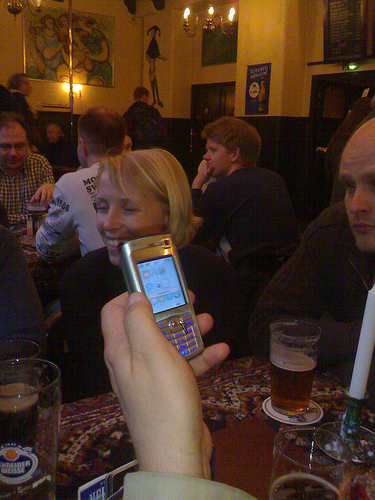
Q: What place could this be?
A: It is a restaurant.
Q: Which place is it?
A: It is a restaurant.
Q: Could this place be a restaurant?
A: Yes, it is a restaurant.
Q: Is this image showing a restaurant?
A: Yes, it is showing a restaurant.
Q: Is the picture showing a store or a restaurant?
A: It is showing a restaurant.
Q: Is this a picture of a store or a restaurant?
A: It is showing a restaurant.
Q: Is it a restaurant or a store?
A: It is a restaurant.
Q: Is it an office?
A: No, it is a restaurant.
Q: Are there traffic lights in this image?
A: No, there are no traffic lights.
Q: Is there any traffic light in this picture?
A: No, there are no traffic lights.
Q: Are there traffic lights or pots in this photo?
A: No, there are no traffic lights or pots.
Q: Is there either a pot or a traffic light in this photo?
A: No, there are no traffic lights or pots.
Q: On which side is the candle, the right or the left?
A: The candle is on the right of the image.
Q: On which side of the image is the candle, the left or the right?
A: The candle is on the right of the image.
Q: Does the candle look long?
A: Yes, the candle is long.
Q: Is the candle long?
A: Yes, the candle is long.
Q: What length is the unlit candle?
A: The candle is long.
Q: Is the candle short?
A: No, the candle is long.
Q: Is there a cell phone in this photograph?
A: Yes, there is a cell phone.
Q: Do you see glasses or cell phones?
A: Yes, there is a cell phone.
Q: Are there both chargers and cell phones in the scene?
A: No, there is a cell phone but no chargers.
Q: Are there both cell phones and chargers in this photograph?
A: No, there is a cell phone but no chargers.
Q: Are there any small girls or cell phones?
A: Yes, there is a small cell phone.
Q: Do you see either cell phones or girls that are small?
A: Yes, the cell phone is small.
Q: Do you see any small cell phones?
A: Yes, there is a small cell phone.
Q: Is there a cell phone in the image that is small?
A: Yes, there is a cell phone that is small.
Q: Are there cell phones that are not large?
A: Yes, there is a small cell phone.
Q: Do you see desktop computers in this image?
A: No, there are no desktop computers.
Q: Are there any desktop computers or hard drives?
A: No, there are no desktop computers or hard drives.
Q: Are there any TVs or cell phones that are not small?
A: No, there is a cell phone but it is small.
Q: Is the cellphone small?
A: Yes, the cellphone is small.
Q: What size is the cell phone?
A: The cell phone is small.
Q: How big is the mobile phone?
A: The mobile phone is small.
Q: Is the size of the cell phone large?
A: No, the cell phone is small.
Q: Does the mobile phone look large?
A: No, the mobile phone is small.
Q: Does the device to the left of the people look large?
A: No, the mobile phone is small.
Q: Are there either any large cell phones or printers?
A: No, there is a cell phone but it is small.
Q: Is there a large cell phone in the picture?
A: No, there is a cell phone but it is small.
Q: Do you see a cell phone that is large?
A: No, there is a cell phone but it is small.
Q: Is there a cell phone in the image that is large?
A: No, there is a cell phone but it is small.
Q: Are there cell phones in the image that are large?
A: No, there is a cell phone but it is small.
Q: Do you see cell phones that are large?
A: No, there is a cell phone but it is small.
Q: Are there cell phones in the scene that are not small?
A: No, there is a cell phone but it is small.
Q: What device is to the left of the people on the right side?
A: The device is a cell phone.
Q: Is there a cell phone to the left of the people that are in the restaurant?
A: Yes, there is a cell phone to the left of the people.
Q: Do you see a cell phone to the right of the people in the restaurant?
A: No, the cell phone is to the left of the people.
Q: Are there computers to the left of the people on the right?
A: No, there is a cell phone to the left of the people.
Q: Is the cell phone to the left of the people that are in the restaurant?
A: Yes, the cell phone is to the left of the people.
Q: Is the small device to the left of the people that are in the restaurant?
A: Yes, the cell phone is to the left of the people.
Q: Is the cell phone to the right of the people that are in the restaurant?
A: No, the cell phone is to the left of the people.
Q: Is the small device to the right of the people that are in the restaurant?
A: No, the cell phone is to the left of the people.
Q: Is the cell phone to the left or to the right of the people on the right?
A: The cell phone is to the left of the people.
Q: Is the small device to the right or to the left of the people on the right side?
A: The cell phone is to the left of the people.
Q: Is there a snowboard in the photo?
A: No, there are no snowboards.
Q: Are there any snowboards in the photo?
A: No, there are no snowboards.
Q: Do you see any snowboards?
A: No, there are no snowboards.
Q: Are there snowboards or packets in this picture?
A: No, there are no snowboards or packets.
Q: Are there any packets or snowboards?
A: No, there are no snowboards or packets.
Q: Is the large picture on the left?
A: Yes, the picture is on the left of the image.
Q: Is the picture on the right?
A: No, the picture is on the left of the image.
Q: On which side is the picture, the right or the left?
A: The picture is on the left of the image.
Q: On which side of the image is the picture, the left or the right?
A: The picture is on the left of the image.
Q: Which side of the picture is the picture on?
A: The picture is on the left of the image.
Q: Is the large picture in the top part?
A: Yes, the picture is in the top of the image.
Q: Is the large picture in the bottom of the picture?
A: No, the picture is in the top of the image.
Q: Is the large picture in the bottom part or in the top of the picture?
A: The picture is in the top of the image.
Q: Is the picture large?
A: Yes, the picture is large.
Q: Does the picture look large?
A: Yes, the picture is large.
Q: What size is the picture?
A: The picture is large.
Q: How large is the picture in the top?
A: The picture is large.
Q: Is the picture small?
A: No, the picture is large.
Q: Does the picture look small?
A: No, the picture is large.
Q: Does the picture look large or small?
A: The picture is large.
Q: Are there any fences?
A: No, there are no fences.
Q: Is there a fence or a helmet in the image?
A: No, there are no fences or helmets.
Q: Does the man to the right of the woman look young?
A: Yes, the man is young.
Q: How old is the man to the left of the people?
A: The man is young.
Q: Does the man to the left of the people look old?
A: No, the man is young.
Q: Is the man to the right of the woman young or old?
A: The man is young.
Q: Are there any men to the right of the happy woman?
A: Yes, there is a man to the right of the woman.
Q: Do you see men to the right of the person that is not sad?
A: Yes, there is a man to the right of the woman.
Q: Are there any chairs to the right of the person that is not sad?
A: No, there is a man to the right of the woman.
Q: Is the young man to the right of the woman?
A: Yes, the man is to the right of the woman.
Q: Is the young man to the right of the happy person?
A: Yes, the man is to the right of the woman.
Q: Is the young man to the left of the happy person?
A: No, the man is to the right of the woman.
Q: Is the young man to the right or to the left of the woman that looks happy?
A: The man is to the right of the woman.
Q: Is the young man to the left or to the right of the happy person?
A: The man is to the right of the woman.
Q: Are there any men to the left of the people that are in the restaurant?
A: Yes, there is a man to the left of the people.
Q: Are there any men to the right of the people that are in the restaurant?
A: No, the man is to the left of the people.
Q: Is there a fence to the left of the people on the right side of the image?
A: No, there is a man to the left of the people.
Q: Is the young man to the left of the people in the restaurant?
A: Yes, the man is to the left of the people.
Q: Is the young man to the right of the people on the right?
A: No, the man is to the left of the people.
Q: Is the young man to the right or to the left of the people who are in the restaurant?
A: The man is to the left of the people.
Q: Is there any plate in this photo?
A: No, there are no plates.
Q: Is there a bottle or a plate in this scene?
A: No, there are no plates or bottles.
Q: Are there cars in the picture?
A: No, there are no cars.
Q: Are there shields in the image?
A: No, there are no shields.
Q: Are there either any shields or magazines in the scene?
A: No, there are no shields or magazines.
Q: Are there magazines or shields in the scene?
A: No, there are no shields or magazines.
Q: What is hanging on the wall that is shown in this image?
A: The poster is hanging on the wall.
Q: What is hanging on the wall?
A: The poster is hanging on the wall.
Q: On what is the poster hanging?
A: The poster is hanging on the wall.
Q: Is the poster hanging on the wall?
A: Yes, the poster is hanging on the wall.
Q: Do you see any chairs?
A: No, there are no chairs.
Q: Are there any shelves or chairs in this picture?
A: No, there are no chairs or shelves.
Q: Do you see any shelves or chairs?
A: No, there are no chairs or shelves.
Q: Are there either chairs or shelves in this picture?
A: No, there are no chairs or shelves.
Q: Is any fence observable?
A: No, there are no fences.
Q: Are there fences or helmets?
A: No, there are no fences or helmets.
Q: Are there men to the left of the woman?
A: Yes, there is a man to the left of the woman.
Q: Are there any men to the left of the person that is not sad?
A: Yes, there is a man to the left of the woman.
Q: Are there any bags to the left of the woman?
A: No, there is a man to the left of the woman.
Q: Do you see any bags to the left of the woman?
A: No, there is a man to the left of the woman.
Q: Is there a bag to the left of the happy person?
A: No, there is a man to the left of the woman.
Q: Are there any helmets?
A: No, there are no helmets.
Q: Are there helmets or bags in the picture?
A: No, there are no helmets or bags.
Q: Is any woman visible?
A: Yes, there is a woman.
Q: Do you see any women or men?
A: Yes, there is a woman.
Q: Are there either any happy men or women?
A: Yes, there is a happy woman.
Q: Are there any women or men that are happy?
A: Yes, the woman is happy.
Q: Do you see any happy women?
A: Yes, there is a happy woman.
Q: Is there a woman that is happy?
A: Yes, there is a woman that is happy.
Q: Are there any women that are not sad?
A: Yes, there is a happy woman.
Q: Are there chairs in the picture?
A: No, there are no chairs.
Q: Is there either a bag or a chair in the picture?
A: No, there are no chairs or bags.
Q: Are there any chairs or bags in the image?
A: No, there are no chairs or bags.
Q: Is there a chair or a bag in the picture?
A: No, there are no chairs or bags.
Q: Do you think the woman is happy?
A: Yes, the woman is happy.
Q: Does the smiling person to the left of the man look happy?
A: Yes, the woman is happy.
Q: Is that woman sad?
A: No, the woman is happy.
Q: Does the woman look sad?
A: No, the woman is happy.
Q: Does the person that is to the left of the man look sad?
A: No, the woman is happy.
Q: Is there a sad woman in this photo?
A: No, there is a woman but she is happy.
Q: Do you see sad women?
A: No, there is a woman but she is happy.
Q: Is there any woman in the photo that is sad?
A: No, there is a woman but she is happy.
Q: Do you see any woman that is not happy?
A: No, there is a woman but she is happy.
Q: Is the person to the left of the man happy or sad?
A: The woman is happy.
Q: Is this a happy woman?
A: Yes, this is a happy woman.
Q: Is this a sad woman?
A: No, this is a happy woman.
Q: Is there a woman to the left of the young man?
A: Yes, there is a woman to the left of the man.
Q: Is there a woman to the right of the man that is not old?
A: No, the woman is to the left of the man.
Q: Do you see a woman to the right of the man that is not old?
A: No, the woman is to the left of the man.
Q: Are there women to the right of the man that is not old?
A: No, the woman is to the left of the man.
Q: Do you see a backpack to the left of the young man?
A: No, there is a woman to the left of the man.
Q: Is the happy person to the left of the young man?
A: Yes, the woman is to the left of the man.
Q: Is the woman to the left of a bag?
A: No, the woman is to the left of the man.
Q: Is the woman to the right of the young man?
A: No, the woman is to the left of the man.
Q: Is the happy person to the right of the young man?
A: No, the woman is to the left of the man.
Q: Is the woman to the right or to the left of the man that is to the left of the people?
A: The woman is to the left of the man.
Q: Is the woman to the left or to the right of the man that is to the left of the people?
A: The woman is to the left of the man.